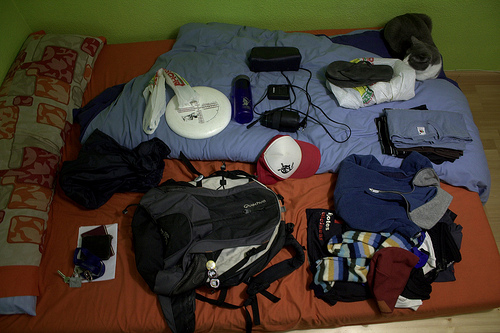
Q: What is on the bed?
A: Things for a trip.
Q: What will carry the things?
A: A backpack.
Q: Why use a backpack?
A: Easy to carry.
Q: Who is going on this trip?
A: A male.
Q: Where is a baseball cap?
A: On the bed.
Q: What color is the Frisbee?
A: White.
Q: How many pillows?
A: 2.